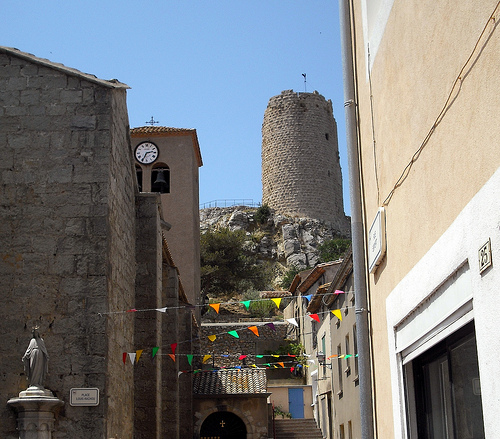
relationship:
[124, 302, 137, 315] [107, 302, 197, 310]
flag hanging on rope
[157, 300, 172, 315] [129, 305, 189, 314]
flag hanging on rope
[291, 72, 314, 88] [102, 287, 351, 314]
flags on rope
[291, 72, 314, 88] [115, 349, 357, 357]
flags on rope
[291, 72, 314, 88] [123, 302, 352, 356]
flags on rope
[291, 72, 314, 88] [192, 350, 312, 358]
flags on rope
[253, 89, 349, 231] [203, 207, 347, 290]
castle on grass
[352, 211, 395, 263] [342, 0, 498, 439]
sign on building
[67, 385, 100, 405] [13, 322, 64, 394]
sign by statue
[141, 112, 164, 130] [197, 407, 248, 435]
cross on doorway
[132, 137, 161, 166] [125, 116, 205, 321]
clock on tower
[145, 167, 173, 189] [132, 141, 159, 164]
bell under clock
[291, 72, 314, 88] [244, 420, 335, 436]
flags across street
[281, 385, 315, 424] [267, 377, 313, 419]
door on building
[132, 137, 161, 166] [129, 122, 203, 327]
clock on tower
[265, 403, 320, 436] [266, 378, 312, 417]
stairway on building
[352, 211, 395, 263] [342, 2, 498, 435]
sign on building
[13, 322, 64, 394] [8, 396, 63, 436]
statue on stand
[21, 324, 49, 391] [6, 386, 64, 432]
statue on stand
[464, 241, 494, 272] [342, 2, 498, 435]
number on building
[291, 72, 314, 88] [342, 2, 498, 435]
flags on building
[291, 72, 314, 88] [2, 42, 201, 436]
flags on building